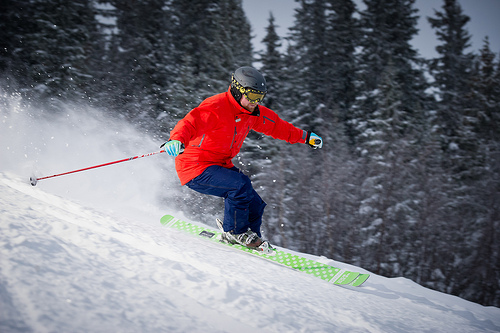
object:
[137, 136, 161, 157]
top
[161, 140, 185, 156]
hand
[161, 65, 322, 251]
man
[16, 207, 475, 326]
snow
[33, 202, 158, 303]
snow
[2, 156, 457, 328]
mountain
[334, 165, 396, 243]
snow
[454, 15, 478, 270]
trees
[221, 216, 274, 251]
white boot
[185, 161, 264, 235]
blue pair of pants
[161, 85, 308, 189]
red jacket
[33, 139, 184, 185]
hand holds the pole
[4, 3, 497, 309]
snow covered trees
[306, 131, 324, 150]
pair of googles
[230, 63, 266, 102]
gray helmet on head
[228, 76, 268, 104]
goggles on his face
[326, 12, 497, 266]
snow on pine trees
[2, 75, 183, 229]
snow spraying in air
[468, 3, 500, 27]
sky is blue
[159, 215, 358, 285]
checkered ski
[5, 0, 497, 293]
snow-capped trees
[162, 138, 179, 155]
blue & yellow gloves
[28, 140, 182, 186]
downhill ski pole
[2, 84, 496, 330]
snow on a mountain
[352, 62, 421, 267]
tree covered by snow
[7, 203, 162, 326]
snow is visible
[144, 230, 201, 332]
snow is visible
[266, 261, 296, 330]
snow is visible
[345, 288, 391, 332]
snow is visible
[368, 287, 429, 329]
snow is visible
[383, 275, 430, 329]
white snow visible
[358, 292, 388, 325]
white snow visible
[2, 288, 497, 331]
white snow visible